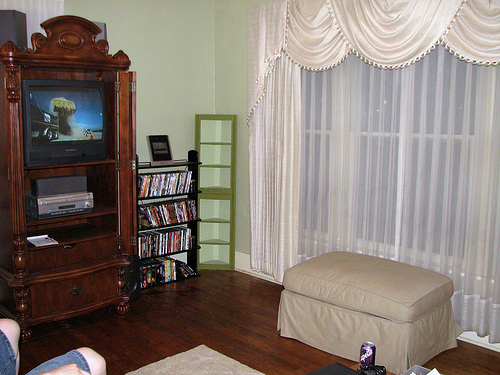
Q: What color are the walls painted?
A: Light green.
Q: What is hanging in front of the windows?
A: Curtains.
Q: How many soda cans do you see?
A: 1.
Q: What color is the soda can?
A: Purple and white.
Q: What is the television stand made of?
A: Wood.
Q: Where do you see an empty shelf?
A: In the corner.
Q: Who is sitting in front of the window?
A: No one.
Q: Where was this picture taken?
A: In the living room.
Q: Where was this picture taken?
A: In the living room.